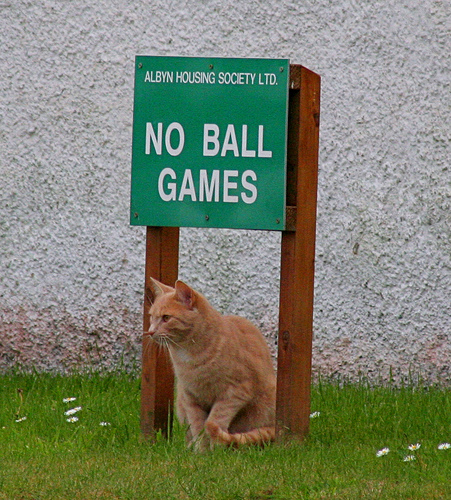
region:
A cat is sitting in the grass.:
[144, 276, 275, 453]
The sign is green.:
[128, 56, 291, 229]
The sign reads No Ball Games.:
[144, 122, 270, 203]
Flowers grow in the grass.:
[61, 396, 80, 423]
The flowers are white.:
[63, 396, 80, 423]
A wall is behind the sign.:
[335, 2, 447, 250]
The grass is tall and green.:
[331, 399, 443, 431]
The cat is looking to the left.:
[147, 312, 172, 323]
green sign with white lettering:
[128, 53, 291, 232]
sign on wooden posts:
[133, 56, 315, 443]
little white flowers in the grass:
[369, 432, 450, 469]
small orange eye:
[156, 311, 171, 324]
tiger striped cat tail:
[200, 417, 278, 449]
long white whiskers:
[151, 330, 178, 358]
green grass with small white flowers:
[1, 364, 450, 495]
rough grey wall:
[3, 2, 446, 374]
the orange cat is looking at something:
[136, 278, 286, 448]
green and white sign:
[121, 47, 297, 237]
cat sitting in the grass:
[127, 273, 299, 460]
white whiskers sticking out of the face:
[140, 329, 187, 361]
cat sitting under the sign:
[94, 42, 367, 482]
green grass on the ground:
[1, 371, 449, 499]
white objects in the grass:
[366, 435, 449, 472]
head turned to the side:
[134, 277, 208, 354]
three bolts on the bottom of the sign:
[130, 208, 282, 227]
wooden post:
[270, 67, 336, 441]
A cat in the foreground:
[127, 269, 299, 458]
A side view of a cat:
[131, 271, 223, 354]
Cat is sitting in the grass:
[128, 275, 303, 450]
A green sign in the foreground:
[118, 43, 306, 249]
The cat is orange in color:
[125, 259, 283, 456]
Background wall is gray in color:
[3, 1, 449, 384]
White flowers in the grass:
[11, 383, 446, 478]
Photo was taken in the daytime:
[4, 3, 448, 486]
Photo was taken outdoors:
[2, 2, 448, 489]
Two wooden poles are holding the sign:
[122, 45, 324, 447]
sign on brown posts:
[132, 64, 304, 446]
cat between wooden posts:
[160, 280, 261, 419]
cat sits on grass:
[258, 391, 363, 485]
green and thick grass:
[315, 380, 400, 494]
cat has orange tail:
[205, 432, 287, 471]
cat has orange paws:
[176, 402, 244, 450]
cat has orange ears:
[149, 265, 222, 313]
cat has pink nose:
[134, 314, 191, 337]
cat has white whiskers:
[141, 315, 187, 356]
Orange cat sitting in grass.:
[146, 276, 276, 453]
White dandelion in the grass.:
[59, 395, 77, 407]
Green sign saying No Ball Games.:
[132, 53, 291, 225]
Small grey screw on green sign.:
[136, 59, 144, 68]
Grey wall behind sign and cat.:
[1, 1, 450, 389]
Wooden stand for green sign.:
[142, 55, 321, 445]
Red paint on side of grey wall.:
[1, 305, 449, 388]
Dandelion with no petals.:
[12, 387, 26, 410]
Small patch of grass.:
[0, 368, 449, 497]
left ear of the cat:
[146, 273, 169, 301]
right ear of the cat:
[168, 278, 198, 309]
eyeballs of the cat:
[143, 308, 169, 323]